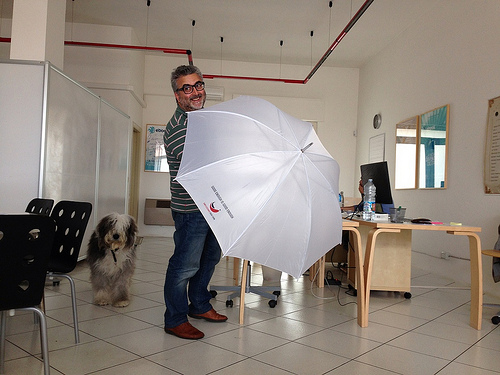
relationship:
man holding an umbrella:
[165, 68, 228, 340] [177, 88, 349, 275]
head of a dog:
[102, 209, 137, 248] [86, 210, 141, 309]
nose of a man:
[191, 88, 198, 98] [164, 62, 226, 339]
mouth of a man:
[188, 94, 204, 102] [164, 62, 226, 339]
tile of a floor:
[249, 340, 350, 374] [0, 236, 499, 373]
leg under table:
[448, 232, 487, 342] [338, 177, 488, 329]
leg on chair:
[68, 274, 80, 345] [38, 200, 91, 274]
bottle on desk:
[363, 178, 377, 220] [233, 208, 485, 328]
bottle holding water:
[356, 171, 384, 219] [359, 173, 381, 223]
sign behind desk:
[394, 104, 453, 191] [227, 208, 486, 325]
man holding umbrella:
[161, 69, 223, 332] [164, 90, 389, 283]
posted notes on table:
[431, 216, 464, 228] [344, 208, 484, 337]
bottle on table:
[363, 178, 377, 220] [341, 181, 470, 278]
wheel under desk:
[401, 290, 412, 300] [233, 208, 485, 328]